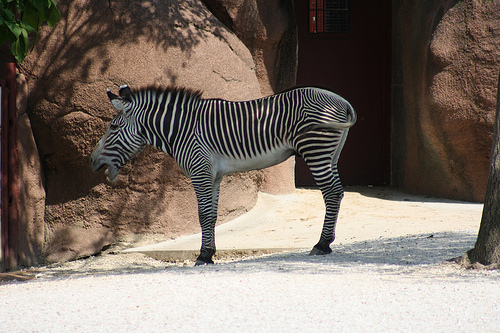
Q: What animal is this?
A: Zebra.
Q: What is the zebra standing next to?
A: Rocks.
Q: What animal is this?
A: Zebra.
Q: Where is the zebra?
A: In front of the boulder.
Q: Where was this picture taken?
A: A zoo.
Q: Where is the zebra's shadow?
A: On the ground.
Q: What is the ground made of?
A: Gravel.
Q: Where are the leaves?
A: Above the zebra.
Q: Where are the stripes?
A: On the zebra.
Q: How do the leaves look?
A: Green and healthy.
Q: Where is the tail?
A: Back end of the zebra.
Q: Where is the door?
A: In between the boulders.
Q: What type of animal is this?
A: Zebra.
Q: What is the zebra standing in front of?
A: Large boulder.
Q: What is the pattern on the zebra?
A: Stripes.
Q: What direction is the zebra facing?
A: Left.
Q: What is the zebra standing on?
A: Sand.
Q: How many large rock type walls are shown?
A: Two.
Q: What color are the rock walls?
A: Brown.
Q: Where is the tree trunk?
A: On the right.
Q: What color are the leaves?
A: Green.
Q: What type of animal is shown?
A: Zebra.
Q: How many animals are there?
A: One.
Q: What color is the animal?
A: Black and white.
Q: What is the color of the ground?
A: White.